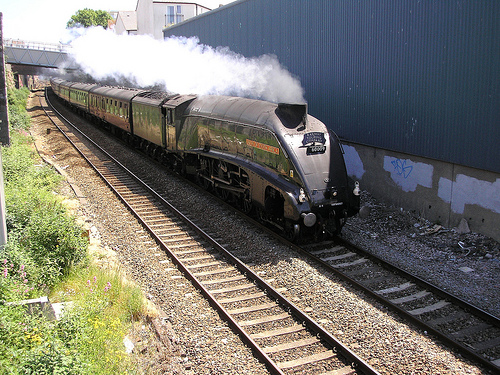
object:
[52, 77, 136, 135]
windows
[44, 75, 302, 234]
right side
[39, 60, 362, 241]
engine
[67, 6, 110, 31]
tree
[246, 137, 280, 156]
label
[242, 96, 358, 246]
front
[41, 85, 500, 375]
track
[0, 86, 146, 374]
green bushes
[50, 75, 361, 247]
train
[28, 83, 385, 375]
brown tracks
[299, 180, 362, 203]
front light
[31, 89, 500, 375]
gravel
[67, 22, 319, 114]
smoke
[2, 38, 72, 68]
bridge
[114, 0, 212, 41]
building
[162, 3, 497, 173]
fence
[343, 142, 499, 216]
patches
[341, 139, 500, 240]
cement fundation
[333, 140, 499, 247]
brick wall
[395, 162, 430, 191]
white brushes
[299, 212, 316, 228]
light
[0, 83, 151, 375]
grass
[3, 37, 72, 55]
rails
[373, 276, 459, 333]
part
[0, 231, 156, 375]
patch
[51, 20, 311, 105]
cloud